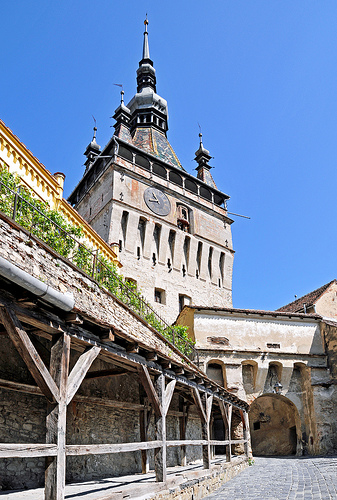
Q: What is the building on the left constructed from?
A: Stone.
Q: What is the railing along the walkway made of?
A: Wood.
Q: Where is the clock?
A: On the tower.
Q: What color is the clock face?
A: Gray.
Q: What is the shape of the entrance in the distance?
A: Arched.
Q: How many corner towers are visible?
A: 3.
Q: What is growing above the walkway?
A: Greenery.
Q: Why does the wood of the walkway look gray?
A: It's weathered.